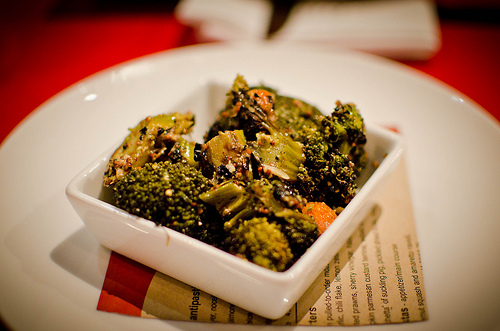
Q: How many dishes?
A: One.